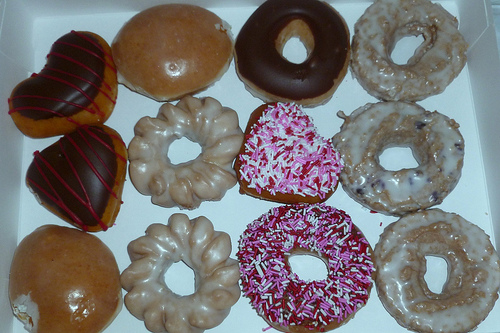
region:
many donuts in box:
[41, 24, 481, 310]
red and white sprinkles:
[233, 193, 339, 308]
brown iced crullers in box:
[110, 104, 242, 192]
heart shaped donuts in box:
[51, 140, 119, 204]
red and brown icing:
[51, 141, 101, 204]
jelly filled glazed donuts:
[108, 13, 219, 86]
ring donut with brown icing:
[227, 8, 326, 84]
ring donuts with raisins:
[334, 96, 483, 208]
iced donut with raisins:
[330, 81, 450, 197]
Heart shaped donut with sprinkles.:
[205, 259, 263, 316]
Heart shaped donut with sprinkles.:
[39, 214, 111, 309]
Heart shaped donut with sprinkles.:
[48, 145, 99, 166]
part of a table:
[248, 203, 260, 233]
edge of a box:
[263, 197, 267, 204]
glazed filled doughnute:
[0, 224, 122, 330]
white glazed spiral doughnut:
[123, 214, 238, 332]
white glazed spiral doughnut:
[126, 96, 242, 208]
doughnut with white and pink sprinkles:
[237, 203, 372, 330]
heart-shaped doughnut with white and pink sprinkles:
[239, 102, 344, 202]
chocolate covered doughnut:
[231, 0, 351, 107]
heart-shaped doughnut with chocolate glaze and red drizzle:
[6, 24, 116, 136]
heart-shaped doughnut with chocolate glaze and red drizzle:
[23, 123, 126, 234]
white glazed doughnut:
[373, 210, 498, 332]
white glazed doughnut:
[350, 0, 469, 103]